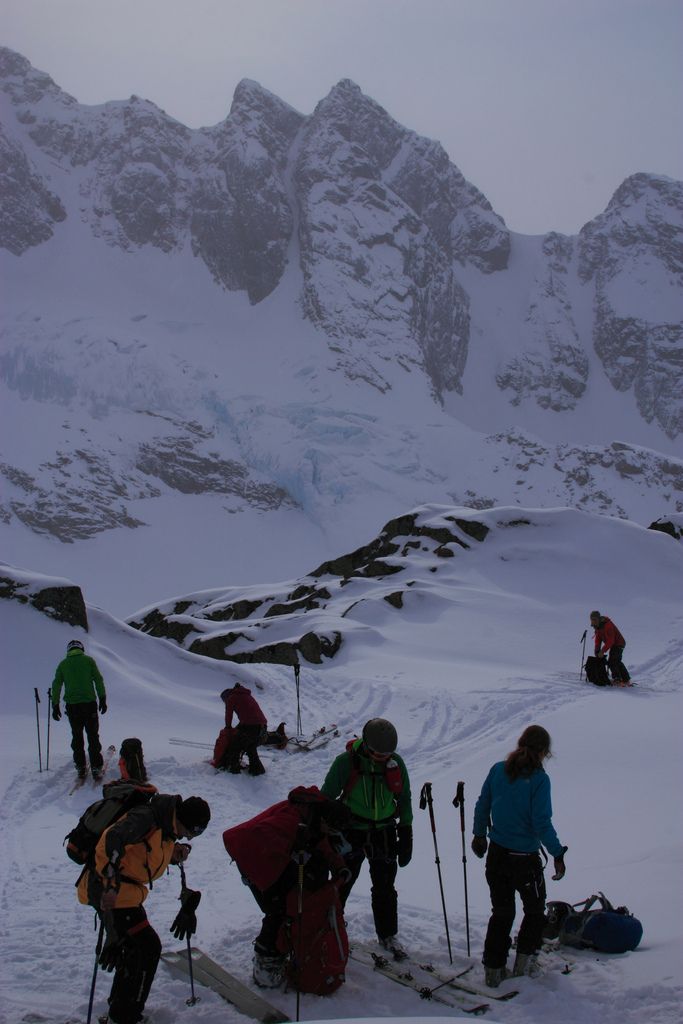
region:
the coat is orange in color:
[116, 816, 173, 883]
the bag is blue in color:
[549, 891, 632, 960]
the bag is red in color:
[292, 888, 360, 974]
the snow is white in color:
[442, 593, 512, 649]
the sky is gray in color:
[431, 26, 558, 118]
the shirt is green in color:
[356, 779, 386, 812]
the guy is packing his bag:
[209, 680, 277, 778]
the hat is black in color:
[181, 794, 216, 835]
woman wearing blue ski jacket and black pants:
[464, 720, 573, 987]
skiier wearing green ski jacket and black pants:
[308, 716, 415, 959]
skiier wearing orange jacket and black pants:
[62, 767, 212, 1022]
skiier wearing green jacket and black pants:
[39, 634, 117, 786]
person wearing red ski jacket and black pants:
[208, 683, 270, 782]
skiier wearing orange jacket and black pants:
[583, 607, 629, 694]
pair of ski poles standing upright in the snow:
[403, 775, 473, 970]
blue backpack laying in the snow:
[558, 892, 645, 960]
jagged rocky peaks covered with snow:
[0, 37, 679, 503]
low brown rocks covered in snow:
[0, 497, 679, 678]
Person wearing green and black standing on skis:
[45, 637, 112, 785]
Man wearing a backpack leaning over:
[63, 780, 207, 1021]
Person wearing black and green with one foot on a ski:
[313, 714, 422, 955]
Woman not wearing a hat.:
[471, 726, 567, 986]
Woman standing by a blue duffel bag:
[471, 725, 645, 982]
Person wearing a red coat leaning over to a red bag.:
[224, 784, 355, 995]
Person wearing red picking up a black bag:
[583, 608, 636, 688]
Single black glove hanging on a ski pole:
[170, 887, 201, 940]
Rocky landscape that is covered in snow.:
[1, 0, 674, 604]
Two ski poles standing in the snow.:
[32, 686, 55, 771]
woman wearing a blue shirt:
[469, 719, 580, 988]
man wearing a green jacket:
[315, 710, 417, 956]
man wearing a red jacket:
[209, 678, 275, 781]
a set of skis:
[346, 940, 521, 1017]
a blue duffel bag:
[553, 890, 650, 959]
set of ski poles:
[412, 775, 475, 969]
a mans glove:
[165, 883, 207, 953]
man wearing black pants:
[44, 633, 115, 785]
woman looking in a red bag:
[219, 778, 364, 1005]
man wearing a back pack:
[53, 772, 221, 1020]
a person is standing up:
[41, 631, 113, 776]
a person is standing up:
[474, 715, 559, 972]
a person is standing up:
[212, 672, 271, 778]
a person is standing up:
[73, 763, 206, 1020]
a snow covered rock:
[195, 619, 343, 667]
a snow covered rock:
[359, 502, 502, 555]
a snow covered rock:
[5, 565, 94, 640]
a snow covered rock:
[627, 504, 680, 548]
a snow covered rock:
[141, 437, 284, 515]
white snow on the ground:
[466, 584, 534, 675]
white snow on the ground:
[624, 715, 661, 748]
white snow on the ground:
[351, 159, 442, 276]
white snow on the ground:
[234, 213, 353, 347]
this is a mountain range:
[81, 124, 579, 932]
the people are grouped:
[87, 666, 573, 978]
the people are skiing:
[1, 609, 627, 964]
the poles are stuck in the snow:
[411, 762, 512, 975]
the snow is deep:
[182, 743, 368, 896]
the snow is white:
[425, 619, 567, 776]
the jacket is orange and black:
[60, 773, 259, 975]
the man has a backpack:
[42, 771, 233, 878]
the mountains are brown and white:
[141, 141, 506, 438]